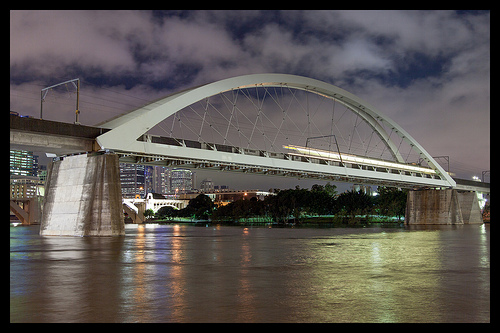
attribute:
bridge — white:
[10, 69, 490, 237]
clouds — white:
[70, 29, 148, 88]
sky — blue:
[147, 56, 197, 93]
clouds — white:
[365, 39, 440, 86]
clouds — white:
[411, 32, 469, 84]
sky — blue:
[18, 13, 475, 158]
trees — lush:
[286, 189, 418, 214]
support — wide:
[36, 150, 129, 238]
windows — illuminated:
[124, 165, 139, 183]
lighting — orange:
[132, 221, 153, 253]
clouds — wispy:
[116, 14, 311, 62]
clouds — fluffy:
[6, 16, 136, 78]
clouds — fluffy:
[160, 17, 247, 66]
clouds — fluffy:
[313, 32, 393, 74]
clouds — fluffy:
[245, 22, 331, 72]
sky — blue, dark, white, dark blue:
[1, 9, 496, 195]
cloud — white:
[146, 14, 251, 74]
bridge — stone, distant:
[8, 195, 192, 227]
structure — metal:
[37, 76, 86, 119]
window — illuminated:
[13, 153, 21, 159]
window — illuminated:
[19, 164, 26, 168]